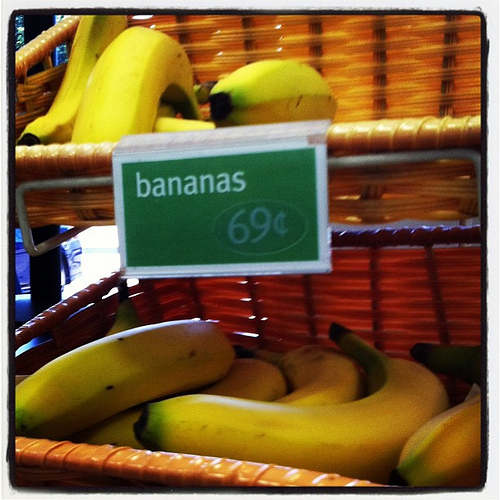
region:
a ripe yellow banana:
[62, 30, 194, 146]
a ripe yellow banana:
[17, 12, 123, 147]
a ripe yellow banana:
[199, 56, 340, 124]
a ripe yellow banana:
[12, 314, 228, 441]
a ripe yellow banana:
[93, 350, 290, 441]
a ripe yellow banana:
[249, 339, 360, 408]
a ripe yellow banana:
[130, 316, 445, 468]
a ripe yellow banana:
[378, 398, 478, 485]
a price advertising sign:
[117, 147, 325, 274]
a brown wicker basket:
[17, 14, 481, 224]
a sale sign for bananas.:
[101, 111, 336, 290]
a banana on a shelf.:
[0, 325, 296, 425]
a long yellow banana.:
[144, 299, 463, 493]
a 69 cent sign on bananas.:
[213, 201, 306, 261]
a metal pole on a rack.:
[17, 205, 88, 333]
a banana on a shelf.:
[194, 46, 357, 127]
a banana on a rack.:
[12, 0, 152, 163]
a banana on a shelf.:
[10, 117, 494, 184]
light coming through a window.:
[61, 222, 144, 295]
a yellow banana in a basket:
[124, 318, 451, 490]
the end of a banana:
[126, 398, 160, 443]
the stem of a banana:
[325, 315, 395, 375]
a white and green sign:
[106, 126, 336, 291]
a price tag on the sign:
[223, 199, 292, 248]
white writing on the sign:
[129, 152, 257, 211]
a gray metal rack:
[13, 147, 485, 262]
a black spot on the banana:
[101, 377, 121, 392]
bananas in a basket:
[9, 292, 486, 489]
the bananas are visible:
[130, 332, 353, 488]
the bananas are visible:
[99, 267, 321, 434]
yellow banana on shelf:
[211, 62, 335, 110]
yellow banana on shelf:
[87, 29, 187, 139]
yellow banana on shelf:
[29, 40, 71, 152]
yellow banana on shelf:
[251, 394, 400, 469]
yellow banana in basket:
[388, 400, 475, 478]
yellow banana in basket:
[15, 323, 217, 394]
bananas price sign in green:
[123, 139, 339, 266]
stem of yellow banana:
[325, 317, 368, 357]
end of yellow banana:
[132, 400, 159, 441]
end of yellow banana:
[193, 80, 243, 117]